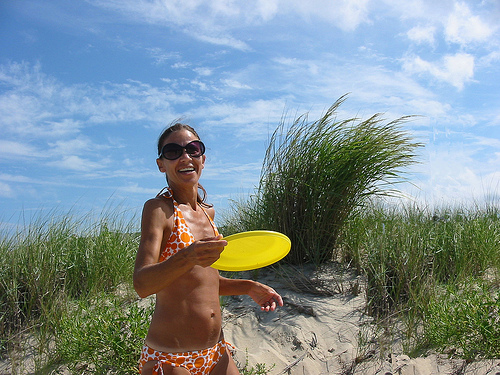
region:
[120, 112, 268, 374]
girl holding yellow frisbee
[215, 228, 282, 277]
yellow frisbee in hand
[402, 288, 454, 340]
patch of green grass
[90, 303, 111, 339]
patch of green grass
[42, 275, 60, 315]
patch of green grass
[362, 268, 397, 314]
patch of green grass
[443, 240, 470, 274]
patch of green grass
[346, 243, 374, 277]
patch of green grass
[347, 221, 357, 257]
patch of green grass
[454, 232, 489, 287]
patch of green grass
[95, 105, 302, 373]
a happy woman wearing sunglsses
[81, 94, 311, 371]
a woman wearing an orange and white swimsuit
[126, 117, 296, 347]
a woman holding a yellow frisbee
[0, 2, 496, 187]
a bright blue sky with a few white clouds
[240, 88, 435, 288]
some tall green grass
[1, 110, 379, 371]
a woman standing in front of a sand dune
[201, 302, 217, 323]
a tiny belly button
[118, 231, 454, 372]
a patch of sand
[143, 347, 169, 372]
the tie of an orange bikini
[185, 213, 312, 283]
a yellow frisbee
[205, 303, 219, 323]
a woman's belly button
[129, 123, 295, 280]
a woman holding a yellow frisbee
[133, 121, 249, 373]
a woman standing outside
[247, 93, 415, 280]
tall green bush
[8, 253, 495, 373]
brown sand on the ground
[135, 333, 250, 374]
orange bikini bottoms on a woman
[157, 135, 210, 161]
large sunglasses on a woman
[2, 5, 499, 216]
blue sky above filled with clouds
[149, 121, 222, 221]
a woman smiling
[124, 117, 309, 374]
the woman at the beach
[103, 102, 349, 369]
the woman holding the frisbee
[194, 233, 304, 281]
the frisbee is yellow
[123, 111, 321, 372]
the woman throwing the frisbee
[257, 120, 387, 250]
the tall patch of grass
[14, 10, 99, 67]
the clear blue sky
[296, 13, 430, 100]
the clouds in the sky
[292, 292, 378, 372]
the sand at the beach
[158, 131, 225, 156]
the woman wearing glasses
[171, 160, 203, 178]
the woman is smiling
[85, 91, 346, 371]
A person is at the beach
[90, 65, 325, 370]
A woman is in a coastal area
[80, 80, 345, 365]
A woman is playing in the sand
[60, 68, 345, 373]
A woman is having fun in the sand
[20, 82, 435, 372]
The woman is at the beach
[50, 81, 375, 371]
A woman is playing with the frisbee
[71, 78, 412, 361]
A woman is going to throw a frisbee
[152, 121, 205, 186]
A woman has sunglasses on her head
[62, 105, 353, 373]
A person is holding a yellow Frisbee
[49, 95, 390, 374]
A person playing Frisbee with a friend